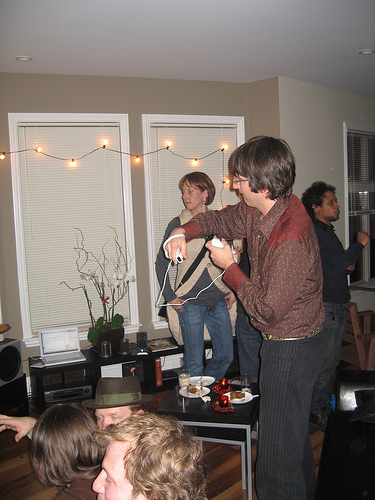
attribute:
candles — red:
[208, 368, 237, 417]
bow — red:
[98, 280, 121, 309]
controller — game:
[188, 229, 235, 272]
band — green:
[90, 388, 142, 407]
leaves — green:
[83, 311, 145, 344]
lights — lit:
[21, 99, 334, 127]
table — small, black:
[143, 380, 267, 463]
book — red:
[144, 349, 159, 394]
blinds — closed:
[19, 116, 159, 323]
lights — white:
[25, 110, 237, 193]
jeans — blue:
[185, 298, 244, 399]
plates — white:
[176, 370, 267, 420]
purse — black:
[166, 231, 236, 323]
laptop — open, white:
[34, 326, 106, 358]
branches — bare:
[63, 218, 140, 316]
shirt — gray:
[313, 223, 361, 318]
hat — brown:
[81, 380, 161, 430]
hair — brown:
[238, 134, 326, 207]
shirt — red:
[236, 191, 320, 330]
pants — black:
[251, 330, 312, 468]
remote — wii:
[188, 229, 236, 262]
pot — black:
[90, 318, 130, 363]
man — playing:
[213, 134, 373, 429]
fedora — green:
[82, 380, 161, 425]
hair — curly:
[316, 203, 345, 232]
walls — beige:
[235, 74, 341, 165]